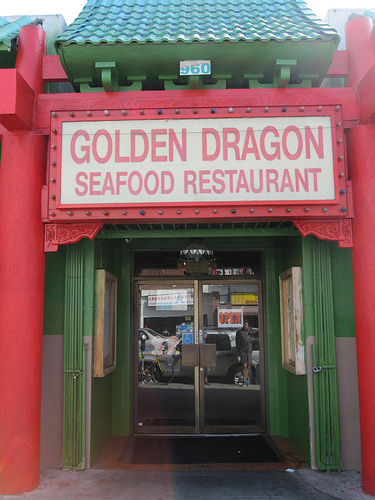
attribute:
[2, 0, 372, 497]
restaurant — asian, open for business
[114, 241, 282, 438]
trim — green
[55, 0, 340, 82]
top — green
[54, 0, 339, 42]
roof — far eastern design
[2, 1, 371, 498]
diner — handicap accessible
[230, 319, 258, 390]
man — standing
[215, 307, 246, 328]
open sign — red, white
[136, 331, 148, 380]
parking meter — black, gray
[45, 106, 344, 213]
sign — red, white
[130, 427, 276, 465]
door mat — large, black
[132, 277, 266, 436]
doors — closed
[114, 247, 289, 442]
door frame — green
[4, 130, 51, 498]
pole — large, red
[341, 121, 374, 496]
pole — large, red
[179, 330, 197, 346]
handicapped sign — blue, white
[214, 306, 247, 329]
sign — saying open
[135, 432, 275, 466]
mat — to wipe feet on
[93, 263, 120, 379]
bulletin board — displaying info, enclosed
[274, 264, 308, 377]
bulletin board — displaying info, enclosed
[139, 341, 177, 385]
bicycle — orange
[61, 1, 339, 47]
tiles — painted green, eastern style, clay, traditional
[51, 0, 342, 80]
awning — green